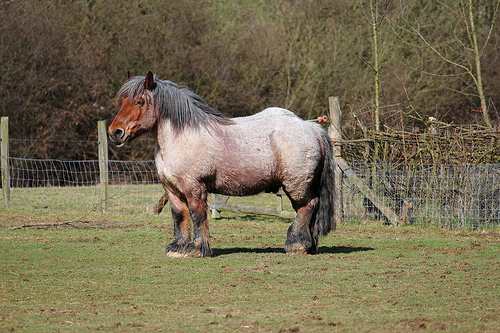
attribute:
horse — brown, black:
[110, 73, 354, 261]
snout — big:
[99, 117, 133, 149]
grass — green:
[50, 284, 87, 309]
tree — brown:
[107, 19, 148, 44]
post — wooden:
[91, 116, 113, 204]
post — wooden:
[323, 93, 339, 229]